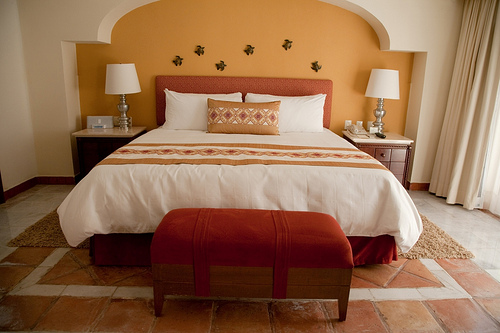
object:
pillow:
[160, 87, 242, 130]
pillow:
[244, 92, 327, 133]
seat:
[149, 207, 354, 321]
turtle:
[172, 56, 184, 67]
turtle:
[194, 45, 205, 56]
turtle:
[215, 60, 227, 71]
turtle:
[243, 44, 255, 55]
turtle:
[282, 39, 293, 51]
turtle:
[310, 61, 322, 73]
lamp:
[104, 63, 142, 130]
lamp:
[364, 68, 400, 133]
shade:
[76, 45, 114, 91]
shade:
[353, 69, 373, 95]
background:
[17, 0, 465, 190]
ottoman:
[149, 208, 353, 321]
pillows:
[206, 97, 280, 136]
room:
[1, 0, 497, 331]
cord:
[350, 133, 371, 139]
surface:
[340, 129, 414, 143]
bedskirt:
[356, 237, 398, 267]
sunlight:
[140, 20, 492, 300]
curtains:
[427, 1, 499, 210]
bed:
[93, 74, 395, 265]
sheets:
[125, 144, 330, 205]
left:
[341, 68, 415, 188]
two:
[162, 88, 328, 133]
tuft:
[90, 239, 143, 266]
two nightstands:
[71, 126, 415, 188]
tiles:
[385, 265, 482, 332]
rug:
[422, 230, 475, 258]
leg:
[153, 293, 162, 317]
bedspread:
[57, 125, 424, 254]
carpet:
[95, 143, 389, 170]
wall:
[21, 0, 56, 71]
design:
[208, 106, 278, 125]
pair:
[104, 63, 400, 135]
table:
[341, 130, 415, 185]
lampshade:
[363, 69, 399, 101]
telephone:
[345, 123, 371, 139]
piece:
[425, 298, 500, 332]